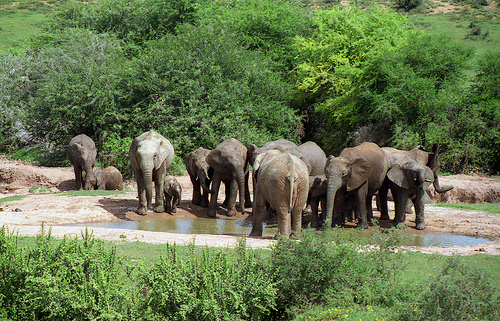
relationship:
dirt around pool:
[70, 196, 203, 220] [79, 172, 498, 264]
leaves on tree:
[297, 22, 393, 106] [335, 22, 459, 127]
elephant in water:
[125, 127, 177, 212] [67, 211, 479, 255]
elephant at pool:
[66, 134, 97, 192] [49, 214, 498, 249]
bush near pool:
[0, 224, 79, 319] [49, 214, 498, 249]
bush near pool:
[22, 226, 150, 319] [49, 214, 498, 249]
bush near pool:
[139, 234, 198, 319] [49, 214, 498, 249]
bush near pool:
[206, 233, 279, 319] [49, 214, 498, 249]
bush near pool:
[270, 222, 344, 312] [49, 214, 498, 249]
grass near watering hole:
[118, 247, 155, 259] [84, 214, 484, 262]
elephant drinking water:
[327, 144, 399, 223] [137, 227, 453, 247]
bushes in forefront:
[136, 237, 281, 319] [15, 209, 483, 305]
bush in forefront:
[22, 226, 150, 319] [15, 209, 483, 305]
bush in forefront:
[266, 222, 356, 319] [15, 209, 483, 305]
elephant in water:
[128, 127, 175, 217] [178, 203, 402, 245]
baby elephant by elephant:
[162, 174, 182, 214] [128, 127, 175, 217]